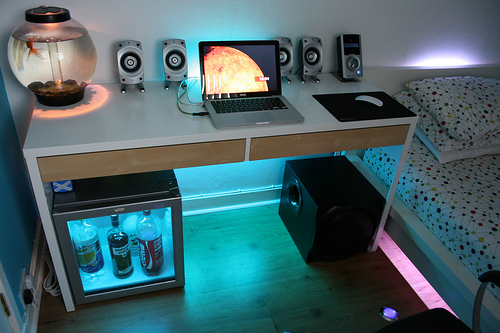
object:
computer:
[198, 40, 305, 129]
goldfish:
[26, 41, 45, 60]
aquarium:
[8, 6, 97, 107]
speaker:
[299, 37, 323, 83]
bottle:
[136, 209, 163, 276]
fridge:
[53, 168, 185, 305]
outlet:
[24, 289, 33, 304]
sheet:
[362, 142, 500, 298]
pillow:
[405, 77, 500, 142]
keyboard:
[210, 97, 288, 113]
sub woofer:
[277, 156, 386, 263]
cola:
[138, 244, 146, 265]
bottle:
[106, 214, 134, 280]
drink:
[109, 237, 127, 244]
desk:
[22, 74, 418, 309]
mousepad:
[311, 91, 416, 122]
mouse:
[355, 96, 384, 107]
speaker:
[162, 38, 188, 91]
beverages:
[70, 218, 105, 280]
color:
[432, 92, 437, 95]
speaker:
[117, 41, 146, 93]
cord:
[42, 252, 61, 297]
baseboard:
[182, 185, 281, 217]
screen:
[203, 45, 276, 94]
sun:
[205, 47, 269, 94]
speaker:
[270, 37, 293, 84]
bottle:
[73, 221, 104, 278]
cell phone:
[380, 306, 399, 322]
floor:
[35, 202, 456, 333]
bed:
[335, 67, 500, 332]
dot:
[437, 208, 441, 213]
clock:
[337, 33, 364, 78]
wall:
[0, 73, 40, 333]